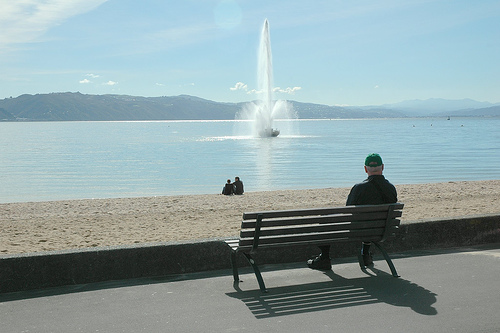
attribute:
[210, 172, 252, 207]
people — sitting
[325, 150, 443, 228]
man — sitting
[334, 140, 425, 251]
man — sitting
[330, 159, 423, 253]
man — sitting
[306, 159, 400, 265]
man — sitting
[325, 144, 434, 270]
man — sitting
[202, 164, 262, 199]
couple — sitting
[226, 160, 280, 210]
couple — sitting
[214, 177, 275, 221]
couple — sitting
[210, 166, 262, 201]
couple — sitting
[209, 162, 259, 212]
people — sitting 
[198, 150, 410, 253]
man — seated